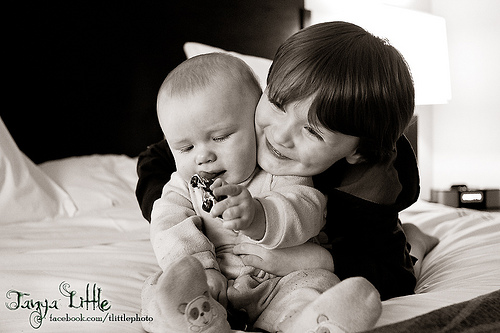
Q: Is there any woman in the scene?
A: No, there are no women.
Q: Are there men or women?
A: No, there are no women or men.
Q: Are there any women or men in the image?
A: No, there are no women or men.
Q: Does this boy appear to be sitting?
A: Yes, the boy is sitting.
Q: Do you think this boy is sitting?
A: Yes, the boy is sitting.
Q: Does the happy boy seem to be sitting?
A: Yes, the boy is sitting.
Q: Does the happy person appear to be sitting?
A: Yes, the boy is sitting.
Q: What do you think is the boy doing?
A: The boy is sitting.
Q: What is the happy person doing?
A: The boy is sitting.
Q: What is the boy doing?
A: The boy is sitting.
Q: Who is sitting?
A: The boy is sitting.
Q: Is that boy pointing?
A: No, the boy is sitting.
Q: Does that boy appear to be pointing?
A: No, the boy is sitting.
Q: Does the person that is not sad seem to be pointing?
A: No, the boy is sitting.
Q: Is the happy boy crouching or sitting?
A: The boy is sitting.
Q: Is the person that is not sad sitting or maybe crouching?
A: The boy is sitting.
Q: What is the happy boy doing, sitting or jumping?
A: The boy is sitting.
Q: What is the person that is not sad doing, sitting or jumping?
A: The boy is sitting.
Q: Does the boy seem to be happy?
A: Yes, the boy is happy.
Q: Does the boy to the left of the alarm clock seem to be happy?
A: Yes, the boy is happy.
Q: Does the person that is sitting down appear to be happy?
A: Yes, the boy is happy.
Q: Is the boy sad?
A: No, the boy is happy.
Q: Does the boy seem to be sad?
A: No, the boy is happy.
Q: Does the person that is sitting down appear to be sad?
A: No, the boy is happy.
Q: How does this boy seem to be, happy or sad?
A: The boy is happy.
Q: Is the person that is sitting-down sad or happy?
A: The boy is happy.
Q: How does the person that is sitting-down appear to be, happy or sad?
A: The boy is happy.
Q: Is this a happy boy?
A: Yes, this is a happy boy.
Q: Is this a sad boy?
A: No, this is a happy boy.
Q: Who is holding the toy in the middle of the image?
A: The boy is holding the toy car.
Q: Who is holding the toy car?
A: The boy is holding the toy car.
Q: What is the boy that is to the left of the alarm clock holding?
A: The boy is holding the toy car.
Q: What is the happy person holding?
A: The boy is holding the toy car.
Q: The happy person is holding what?
A: The boy is holding the toy car.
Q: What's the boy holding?
A: The boy is holding the toy car.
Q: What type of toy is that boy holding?
A: The boy is holding the toy car.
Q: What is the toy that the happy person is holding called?
A: The toy is a toy car.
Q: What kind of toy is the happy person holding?
A: The boy is holding the toy car.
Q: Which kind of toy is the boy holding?
A: The boy is holding the toy car.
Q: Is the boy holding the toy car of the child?
A: Yes, the boy is holding the toy car.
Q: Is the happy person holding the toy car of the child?
A: Yes, the boy is holding the toy car.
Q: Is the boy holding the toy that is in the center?
A: Yes, the boy is holding the toy car.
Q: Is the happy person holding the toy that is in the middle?
A: Yes, the boy is holding the toy car.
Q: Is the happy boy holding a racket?
A: No, the boy is holding the toy car.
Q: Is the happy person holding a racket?
A: No, the boy is holding the toy car.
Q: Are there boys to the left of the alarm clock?
A: Yes, there is a boy to the left of the alarm clock.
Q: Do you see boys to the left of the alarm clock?
A: Yes, there is a boy to the left of the alarm clock.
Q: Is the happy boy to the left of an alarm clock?
A: Yes, the boy is to the left of an alarm clock.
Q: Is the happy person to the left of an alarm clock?
A: Yes, the boy is to the left of an alarm clock.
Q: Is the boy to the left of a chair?
A: No, the boy is to the left of an alarm clock.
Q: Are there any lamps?
A: Yes, there is a lamp.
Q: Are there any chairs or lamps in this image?
A: Yes, there is a lamp.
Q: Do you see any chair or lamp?
A: Yes, there is a lamp.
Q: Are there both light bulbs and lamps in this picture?
A: No, there is a lamp but no light bulbs.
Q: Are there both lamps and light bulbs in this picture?
A: No, there is a lamp but no light bulbs.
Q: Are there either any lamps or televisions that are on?
A: Yes, the lamp is on.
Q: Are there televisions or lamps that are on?
A: Yes, the lamp is on.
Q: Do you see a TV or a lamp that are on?
A: Yes, the lamp is on.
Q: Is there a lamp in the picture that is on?
A: Yes, there is a lamp that is on.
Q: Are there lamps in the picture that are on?
A: Yes, there is a lamp that is on.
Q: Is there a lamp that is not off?
A: Yes, there is a lamp that is on.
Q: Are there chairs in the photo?
A: No, there are no chairs.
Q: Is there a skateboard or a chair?
A: No, there are no chairs or skateboards.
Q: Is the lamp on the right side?
A: Yes, the lamp is on the right of the image.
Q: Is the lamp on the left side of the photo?
A: No, the lamp is on the right of the image.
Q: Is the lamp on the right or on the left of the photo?
A: The lamp is on the right of the image.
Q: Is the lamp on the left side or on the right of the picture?
A: The lamp is on the right of the image.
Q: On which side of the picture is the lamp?
A: The lamp is on the right of the image.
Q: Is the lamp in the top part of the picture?
A: Yes, the lamp is in the top of the image.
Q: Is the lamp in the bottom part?
A: No, the lamp is in the top of the image.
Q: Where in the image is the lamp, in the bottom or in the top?
A: The lamp is in the top of the image.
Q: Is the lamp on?
A: Yes, the lamp is on.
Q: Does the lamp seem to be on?
A: Yes, the lamp is on.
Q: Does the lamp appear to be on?
A: Yes, the lamp is on.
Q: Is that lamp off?
A: No, the lamp is on.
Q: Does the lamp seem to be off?
A: No, the lamp is on.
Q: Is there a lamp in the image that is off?
A: No, there is a lamp but it is on.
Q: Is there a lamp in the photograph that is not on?
A: No, there is a lamp but it is on.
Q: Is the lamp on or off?
A: The lamp is on.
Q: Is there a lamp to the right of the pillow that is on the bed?
A: Yes, there is a lamp to the right of the pillow.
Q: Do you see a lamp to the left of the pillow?
A: No, the lamp is to the right of the pillow.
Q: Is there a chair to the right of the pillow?
A: No, there is a lamp to the right of the pillow.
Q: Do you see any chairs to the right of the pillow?
A: No, there is a lamp to the right of the pillow.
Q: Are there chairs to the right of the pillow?
A: No, there is a lamp to the right of the pillow.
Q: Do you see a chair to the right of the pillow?
A: No, there is a lamp to the right of the pillow.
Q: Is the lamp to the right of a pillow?
A: Yes, the lamp is to the right of a pillow.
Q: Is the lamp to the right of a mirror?
A: No, the lamp is to the right of a pillow.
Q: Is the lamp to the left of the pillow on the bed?
A: No, the lamp is to the right of the pillow.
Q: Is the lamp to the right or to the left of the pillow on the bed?
A: The lamp is to the right of the pillow.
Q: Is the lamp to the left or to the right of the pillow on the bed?
A: The lamp is to the right of the pillow.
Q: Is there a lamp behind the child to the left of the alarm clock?
A: Yes, there is a lamp behind the kid.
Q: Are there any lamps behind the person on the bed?
A: Yes, there is a lamp behind the kid.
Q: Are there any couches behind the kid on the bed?
A: No, there is a lamp behind the kid.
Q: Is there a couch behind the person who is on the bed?
A: No, there is a lamp behind the kid.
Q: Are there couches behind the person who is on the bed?
A: No, there is a lamp behind the kid.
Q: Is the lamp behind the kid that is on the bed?
A: Yes, the lamp is behind the child.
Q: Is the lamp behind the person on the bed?
A: Yes, the lamp is behind the child.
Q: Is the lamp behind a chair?
A: No, the lamp is behind the child.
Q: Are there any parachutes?
A: No, there are no parachutes.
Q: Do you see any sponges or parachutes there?
A: No, there are no parachutes or sponges.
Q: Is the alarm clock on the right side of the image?
A: Yes, the alarm clock is on the right of the image.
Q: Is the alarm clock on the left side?
A: No, the alarm clock is on the right of the image.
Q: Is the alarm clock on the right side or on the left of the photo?
A: The alarm clock is on the right of the image.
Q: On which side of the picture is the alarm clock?
A: The alarm clock is on the right of the image.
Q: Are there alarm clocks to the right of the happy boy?
A: Yes, there is an alarm clock to the right of the boy.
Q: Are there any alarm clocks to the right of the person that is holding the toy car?
A: Yes, there is an alarm clock to the right of the boy.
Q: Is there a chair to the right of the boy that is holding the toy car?
A: No, there is an alarm clock to the right of the boy.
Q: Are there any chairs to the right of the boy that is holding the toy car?
A: No, there is an alarm clock to the right of the boy.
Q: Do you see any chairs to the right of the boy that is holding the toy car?
A: No, there is an alarm clock to the right of the boy.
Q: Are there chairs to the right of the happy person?
A: No, there is an alarm clock to the right of the boy.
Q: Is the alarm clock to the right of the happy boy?
A: Yes, the alarm clock is to the right of the boy.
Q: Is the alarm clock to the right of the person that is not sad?
A: Yes, the alarm clock is to the right of the boy.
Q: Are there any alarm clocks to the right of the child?
A: Yes, there is an alarm clock to the right of the child.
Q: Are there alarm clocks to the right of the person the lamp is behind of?
A: Yes, there is an alarm clock to the right of the child.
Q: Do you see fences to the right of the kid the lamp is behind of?
A: No, there is an alarm clock to the right of the kid.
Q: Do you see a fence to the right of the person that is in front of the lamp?
A: No, there is an alarm clock to the right of the kid.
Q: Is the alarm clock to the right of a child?
A: Yes, the alarm clock is to the right of a child.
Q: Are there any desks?
A: No, there are no desks.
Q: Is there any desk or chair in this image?
A: No, there are no desks or chairs.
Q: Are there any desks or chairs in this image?
A: No, there are no desks or chairs.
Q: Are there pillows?
A: Yes, there is a pillow.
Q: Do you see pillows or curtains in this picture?
A: Yes, there is a pillow.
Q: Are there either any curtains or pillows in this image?
A: Yes, there is a pillow.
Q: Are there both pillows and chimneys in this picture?
A: No, there is a pillow but no chimneys.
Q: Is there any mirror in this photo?
A: No, there are no mirrors.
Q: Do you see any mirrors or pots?
A: No, there are no mirrors or pots.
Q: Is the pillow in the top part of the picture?
A: Yes, the pillow is in the top of the image.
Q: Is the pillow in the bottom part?
A: No, the pillow is in the top of the image.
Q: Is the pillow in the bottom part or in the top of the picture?
A: The pillow is in the top of the image.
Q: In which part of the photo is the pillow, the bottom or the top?
A: The pillow is in the top of the image.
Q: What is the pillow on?
A: The pillow is on the bed.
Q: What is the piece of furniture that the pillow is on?
A: The piece of furniture is a bed.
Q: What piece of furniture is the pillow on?
A: The pillow is on the bed.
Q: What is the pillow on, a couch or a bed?
A: The pillow is on a bed.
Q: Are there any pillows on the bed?
A: Yes, there is a pillow on the bed.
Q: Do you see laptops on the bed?
A: No, there is a pillow on the bed.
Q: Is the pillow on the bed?
A: Yes, the pillow is on the bed.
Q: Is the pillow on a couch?
A: No, the pillow is on the bed.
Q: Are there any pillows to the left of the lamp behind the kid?
A: Yes, there is a pillow to the left of the lamp.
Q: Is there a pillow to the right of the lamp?
A: No, the pillow is to the left of the lamp.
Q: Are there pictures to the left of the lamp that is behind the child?
A: No, there is a pillow to the left of the lamp.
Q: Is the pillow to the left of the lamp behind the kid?
A: Yes, the pillow is to the left of the lamp.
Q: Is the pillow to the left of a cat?
A: No, the pillow is to the left of the lamp.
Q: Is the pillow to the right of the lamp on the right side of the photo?
A: No, the pillow is to the left of the lamp.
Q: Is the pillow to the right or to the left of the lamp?
A: The pillow is to the left of the lamp.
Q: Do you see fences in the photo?
A: No, there are no fences.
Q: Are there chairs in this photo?
A: No, there are no chairs.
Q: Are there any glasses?
A: No, there are no glasses.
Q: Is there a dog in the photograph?
A: No, there are no dogs.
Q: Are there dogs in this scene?
A: No, there are no dogs.